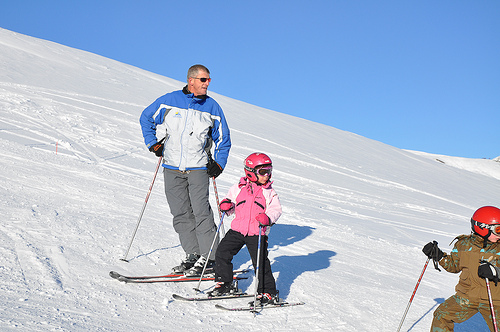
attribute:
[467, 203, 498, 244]
helmet — red, black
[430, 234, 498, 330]
jacket — brown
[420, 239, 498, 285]
gloves — black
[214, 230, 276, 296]
pants — black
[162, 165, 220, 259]
pants — gray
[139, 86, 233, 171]
jacket — blue, white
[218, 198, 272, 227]
gloves — red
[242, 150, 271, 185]
helmet — pink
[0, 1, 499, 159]
sky — blue, clear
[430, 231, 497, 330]
ski suit — brown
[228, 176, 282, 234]
ski jacket — pink, black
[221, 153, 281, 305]
girl — skiing, young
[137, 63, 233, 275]
man — skiing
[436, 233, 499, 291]
coat — brown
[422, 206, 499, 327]
boy — skiing, young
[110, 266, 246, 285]
skis — red, black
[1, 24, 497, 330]
mountain — white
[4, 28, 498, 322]
ground — white, powdery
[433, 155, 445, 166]
rocks — black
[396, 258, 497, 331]
pole — red, silver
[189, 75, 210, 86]
goggles — black